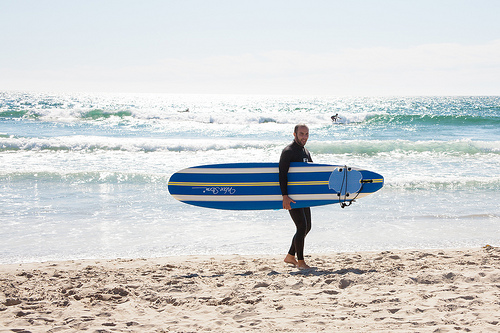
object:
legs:
[286, 203, 311, 260]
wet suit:
[278, 141, 313, 261]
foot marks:
[124, 262, 197, 286]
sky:
[0, 0, 500, 64]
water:
[0, 94, 500, 269]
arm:
[279, 145, 294, 196]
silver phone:
[165, 158, 392, 216]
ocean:
[0, 94, 498, 247]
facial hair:
[296, 131, 310, 147]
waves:
[0, 95, 500, 215]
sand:
[0, 243, 500, 331]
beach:
[0, 244, 499, 332]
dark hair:
[294, 123, 310, 135]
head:
[293, 123, 311, 146]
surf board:
[165, 160, 385, 211]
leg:
[288, 207, 307, 260]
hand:
[281, 195, 296, 210]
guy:
[278, 123, 320, 272]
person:
[331, 113, 342, 122]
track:
[0, 251, 500, 333]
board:
[165, 162, 384, 209]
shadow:
[290, 267, 366, 276]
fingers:
[282, 200, 296, 211]